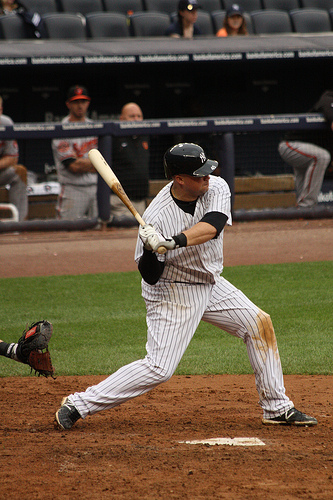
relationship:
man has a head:
[105, 100, 151, 223] [120, 102, 143, 120]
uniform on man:
[66, 173, 295, 420] [55, 141, 318, 431]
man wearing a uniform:
[55, 141, 318, 431] [66, 173, 295, 420]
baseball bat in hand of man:
[89, 149, 167, 255] [55, 138, 317, 426]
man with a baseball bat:
[55, 138, 317, 426] [89, 149, 167, 255]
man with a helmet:
[55, 141, 318, 431] [183, 144, 225, 178]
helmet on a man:
[183, 144, 225, 178] [55, 141, 318, 431]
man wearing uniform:
[55, 138, 317, 426] [66, 173, 295, 420]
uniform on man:
[66, 173, 295, 420] [55, 138, 317, 426]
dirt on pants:
[247, 303, 293, 358] [56, 285, 316, 437]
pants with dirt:
[56, 285, 316, 437] [247, 303, 293, 358]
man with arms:
[51, 83, 100, 223] [54, 139, 97, 174]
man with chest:
[51, 83, 100, 223] [63, 127, 98, 159]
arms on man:
[54, 139, 97, 174] [51, 83, 100, 223]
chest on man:
[63, 127, 98, 159] [51, 83, 100, 223]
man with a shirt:
[105, 100, 151, 223] [109, 128, 152, 204]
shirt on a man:
[109, 128, 152, 204] [105, 100, 151, 223]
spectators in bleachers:
[166, 0, 253, 43] [0, 0, 331, 41]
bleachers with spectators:
[0, 0, 331, 41] [166, 0, 253, 43]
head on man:
[164, 137, 222, 196] [55, 141, 318, 431]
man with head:
[55, 141, 318, 431] [164, 137, 222, 196]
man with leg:
[55, 141, 318, 431] [56, 286, 199, 428]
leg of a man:
[56, 286, 199, 428] [55, 141, 318, 431]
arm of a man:
[175, 214, 233, 257] [55, 141, 318, 431]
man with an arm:
[55, 141, 318, 431] [175, 214, 233, 257]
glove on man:
[148, 231, 175, 252] [55, 138, 317, 426]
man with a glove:
[55, 138, 317, 426] [148, 231, 175, 252]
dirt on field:
[0, 375, 332, 499] [0, 218, 332, 498]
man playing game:
[55, 141, 318, 431] [2, 15, 331, 493]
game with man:
[2, 15, 331, 493] [55, 141, 318, 431]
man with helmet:
[55, 141, 318, 431] [183, 144, 225, 178]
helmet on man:
[183, 144, 225, 178] [55, 141, 318, 431]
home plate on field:
[164, 424, 270, 464] [0, 218, 332, 498]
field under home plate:
[0, 218, 332, 498] [164, 424, 270, 464]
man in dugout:
[51, 83, 99, 219] [3, 81, 332, 180]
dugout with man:
[3, 81, 332, 180] [51, 83, 99, 219]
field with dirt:
[0, 218, 332, 498] [56, 452, 263, 490]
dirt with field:
[56, 452, 263, 490] [0, 218, 332, 498]